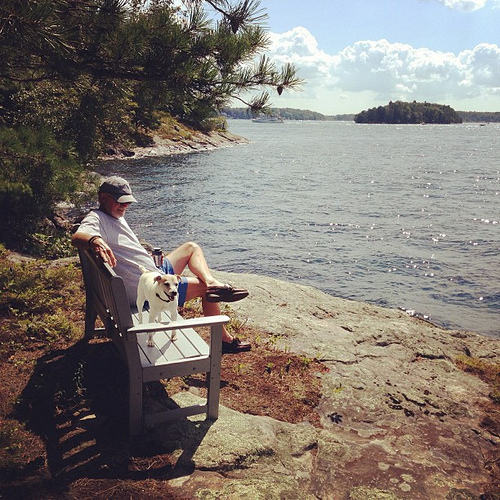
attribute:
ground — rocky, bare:
[0, 244, 499, 499]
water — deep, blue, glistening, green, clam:
[79, 119, 500, 339]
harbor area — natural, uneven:
[62, 148, 227, 270]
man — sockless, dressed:
[70, 175, 253, 354]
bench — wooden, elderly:
[70, 239, 229, 435]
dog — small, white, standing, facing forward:
[135, 262, 184, 346]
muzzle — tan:
[165, 286, 179, 301]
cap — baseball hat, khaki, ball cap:
[99, 176, 137, 207]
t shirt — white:
[76, 209, 165, 307]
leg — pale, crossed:
[168, 241, 249, 304]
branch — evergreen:
[1, 1, 308, 141]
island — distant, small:
[354, 99, 463, 124]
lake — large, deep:
[68, 117, 500, 341]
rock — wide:
[148, 391, 318, 470]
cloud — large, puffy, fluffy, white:
[238, 25, 500, 102]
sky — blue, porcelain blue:
[122, 1, 500, 116]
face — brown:
[154, 274, 183, 301]